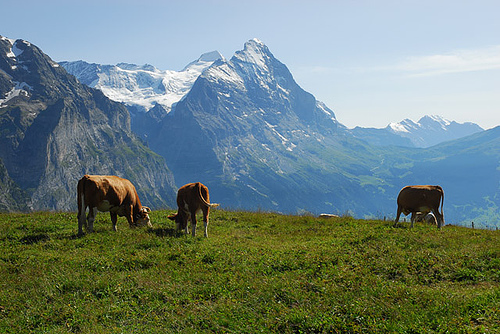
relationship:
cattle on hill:
[394, 185, 445, 228] [4, 205, 498, 332]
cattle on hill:
[77, 174, 153, 238] [4, 205, 498, 332]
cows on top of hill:
[397, 186, 447, 226] [16, 217, 498, 332]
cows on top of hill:
[174, 185, 213, 236] [16, 217, 498, 332]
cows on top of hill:
[78, 175, 153, 230] [16, 217, 498, 332]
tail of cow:
[192, 180, 224, 211] [153, 178, 223, 241]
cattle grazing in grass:
[77, 174, 153, 238] [0, 211, 499, 332]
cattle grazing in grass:
[167, 182, 219, 238] [0, 211, 499, 332]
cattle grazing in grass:
[394, 185, 445, 228] [0, 211, 499, 332]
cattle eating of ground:
[389, 177, 449, 231] [397, 213, 416, 221]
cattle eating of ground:
[159, 177, 219, 242] [170, 232, 184, 241]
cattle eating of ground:
[69, 168, 153, 235] [139, 231, 162, 238]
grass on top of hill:
[0, 211, 499, 332] [4, 205, 498, 332]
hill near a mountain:
[4, 205, 498, 332] [1, 37, 498, 228]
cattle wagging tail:
[167, 182, 219, 238] [195, 183, 220, 208]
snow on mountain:
[89, 50, 230, 115] [48, 49, 232, 147]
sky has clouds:
[51, 21, 497, 132] [351, 36, 478, 112]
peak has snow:
[0, 35, 317, 109] [0, 37, 292, 109]